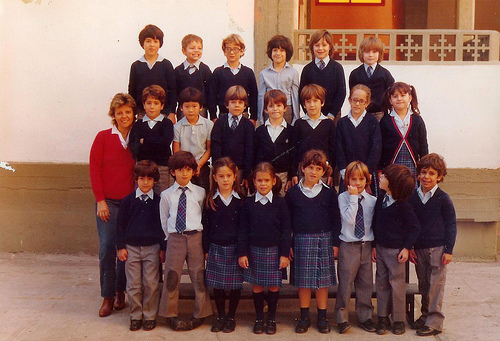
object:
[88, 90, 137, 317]
adult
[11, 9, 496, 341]
class picture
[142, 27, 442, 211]
class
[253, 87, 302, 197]
kids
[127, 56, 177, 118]
uniform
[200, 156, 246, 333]
girls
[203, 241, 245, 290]
skirts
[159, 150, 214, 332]
boys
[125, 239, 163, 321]
khakis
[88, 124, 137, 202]
shirt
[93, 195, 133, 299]
jeans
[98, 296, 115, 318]
boots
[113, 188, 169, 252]
sweater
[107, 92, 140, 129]
hair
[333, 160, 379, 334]
boy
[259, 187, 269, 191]
mouth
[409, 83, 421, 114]
pig tails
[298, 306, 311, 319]
socks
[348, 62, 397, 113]
sweaters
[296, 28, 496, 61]
fence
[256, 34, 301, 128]
kid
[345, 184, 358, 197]
fist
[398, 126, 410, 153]
red outline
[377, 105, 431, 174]
sweater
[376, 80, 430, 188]
girl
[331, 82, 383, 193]
girl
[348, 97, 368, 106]
glasses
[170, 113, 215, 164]
short sleeves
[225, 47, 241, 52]
eyeglasses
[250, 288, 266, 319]
sock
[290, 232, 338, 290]
skirt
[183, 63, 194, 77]
neck tie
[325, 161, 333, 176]
pony tail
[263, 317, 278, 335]
shoe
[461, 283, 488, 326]
pavement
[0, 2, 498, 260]
wall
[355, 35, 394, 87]
young boy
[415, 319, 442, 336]
feet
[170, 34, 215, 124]
boy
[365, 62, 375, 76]
tie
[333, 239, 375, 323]
pants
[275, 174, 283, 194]
pigtails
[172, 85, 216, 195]
boy